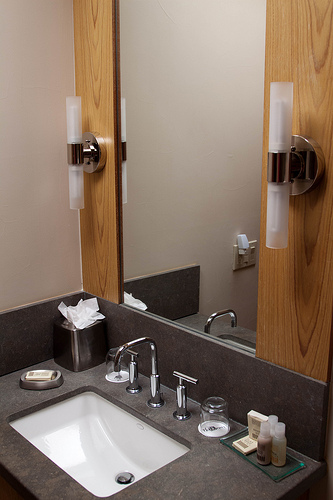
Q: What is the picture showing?
A: It is showing a bathroom.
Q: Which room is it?
A: It is a bathroom.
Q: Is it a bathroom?
A: Yes, it is a bathroom.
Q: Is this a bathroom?
A: Yes, it is a bathroom.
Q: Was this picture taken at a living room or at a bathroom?
A: It was taken at a bathroom.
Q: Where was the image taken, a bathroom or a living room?
A: It was taken at a bathroom.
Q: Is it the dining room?
A: No, it is the bathroom.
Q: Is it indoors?
A: Yes, it is indoors.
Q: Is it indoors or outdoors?
A: It is indoors.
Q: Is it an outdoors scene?
A: No, it is indoors.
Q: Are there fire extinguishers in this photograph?
A: No, there are no fire extinguishers.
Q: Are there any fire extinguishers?
A: No, there are no fire extinguishers.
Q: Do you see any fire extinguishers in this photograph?
A: No, there are no fire extinguishers.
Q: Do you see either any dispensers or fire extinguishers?
A: No, there are no fire extinguishers or dispensers.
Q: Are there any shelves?
A: No, there are no shelves.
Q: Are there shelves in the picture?
A: No, there are no shelves.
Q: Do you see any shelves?
A: No, there are no shelves.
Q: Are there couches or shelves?
A: No, there are no shelves or couches.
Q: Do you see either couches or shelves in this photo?
A: No, there are no shelves or couches.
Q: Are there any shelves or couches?
A: No, there are no shelves or couches.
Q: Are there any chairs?
A: No, there are no chairs.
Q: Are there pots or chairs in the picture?
A: No, there are no chairs or pots.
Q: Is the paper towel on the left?
A: Yes, the paper towel is on the left of the image.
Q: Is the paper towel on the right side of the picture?
A: No, the paper towel is on the left of the image.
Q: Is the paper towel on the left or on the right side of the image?
A: The paper towel is on the left of the image.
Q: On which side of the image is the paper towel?
A: The paper towel is on the left of the image.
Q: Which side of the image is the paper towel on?
A: The paper towel is on the left of the image.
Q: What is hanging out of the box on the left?
A: The paper towel is hanging out of the box.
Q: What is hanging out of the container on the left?
A: The paper towel is hanging out of the box.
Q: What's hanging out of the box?
A: The paper towel is hanging out of the box.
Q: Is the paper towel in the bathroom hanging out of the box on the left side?
A: Yes, the paper towel is hanging out of the box.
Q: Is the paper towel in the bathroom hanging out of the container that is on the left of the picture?
A: Yes, the paper towel is hanging out of the box.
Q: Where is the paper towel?
A: The paper towel is in the bathroom.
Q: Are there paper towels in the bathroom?
A: Yes, there is a paper towel in the bathroom.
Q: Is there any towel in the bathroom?
A: No, there is a paper towel in the bathroom.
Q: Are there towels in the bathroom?
A: No, there is a paper towel in the bathroom.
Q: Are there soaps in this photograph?
A: Yes, there is a soap.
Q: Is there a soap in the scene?
A: Yes, there is a soap.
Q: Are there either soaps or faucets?
A: Yes, there is a soap.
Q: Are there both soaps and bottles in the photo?
A: Yes, there are both a soap and a bottle.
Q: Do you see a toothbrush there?
A: No, there are no toothbrushes.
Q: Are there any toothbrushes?
A: No, there are no toothbrushes.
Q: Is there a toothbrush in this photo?
A: No, there are no toothbrushes.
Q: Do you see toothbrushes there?
A: No, there are no toothbrushes.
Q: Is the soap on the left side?
A: Yes, the soap is on the left of the image.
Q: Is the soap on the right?
A: No, the soap is on the left of the image.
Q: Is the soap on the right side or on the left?
A: The soap is on the left of the image.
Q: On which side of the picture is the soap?
A: The soap is on the left of the image.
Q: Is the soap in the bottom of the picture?
A: Yes, the soap is in the bottom of the image.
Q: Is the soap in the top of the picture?
A: No, the soap is in the bottom of the image.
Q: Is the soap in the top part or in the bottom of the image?
A: The soap is in the bottom of the image.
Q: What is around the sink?
A: The soap is around the sink.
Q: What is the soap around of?
A: The soap is around the sink.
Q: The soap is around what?
A: The soap is around the sink.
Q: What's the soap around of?
A: The soap is around the sink.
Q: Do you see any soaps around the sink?
A: Yes, there is a soap around the sink.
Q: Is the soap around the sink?
A: Yes, the soap is around the sink.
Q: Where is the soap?
A: The soap is in the bathroom.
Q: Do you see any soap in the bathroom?
A: Yes, there is a soap in the bathroom.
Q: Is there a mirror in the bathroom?
A: No, there is a soap in the bathroom.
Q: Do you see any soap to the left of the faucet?
A: Yes, there is a soap to the left of the faucet.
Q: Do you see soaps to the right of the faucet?
A: No, the soap is to the left of the faucet.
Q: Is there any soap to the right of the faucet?
A: No, the soap is to the left of the faucet.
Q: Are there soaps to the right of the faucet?
A: No, the soap is to the left of the faucet.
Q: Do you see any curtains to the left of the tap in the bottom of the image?
A: No, there is a soap to the left of the faucet.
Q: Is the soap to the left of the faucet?
A: Yes, the soap is to the left of the faucet.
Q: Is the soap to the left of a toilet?
A: No, the soap is to the left of the faucet.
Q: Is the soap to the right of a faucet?
A: No, the soap is to the left of a faucet.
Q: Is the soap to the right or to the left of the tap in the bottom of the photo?
A: The soap is to the left of the tap.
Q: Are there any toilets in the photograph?
A: No, there are no toilets.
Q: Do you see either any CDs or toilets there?
A: No, there are no toilets or cds.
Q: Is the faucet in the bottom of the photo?
A: Yes, the faucet is in the bottom of the image.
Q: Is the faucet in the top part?
A: No, the faucet is in the bottom of the image.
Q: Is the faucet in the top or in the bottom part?
A: The faucet is in the bottom of the image.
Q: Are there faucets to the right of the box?
A: Yes, there is a faucet to the right of the box.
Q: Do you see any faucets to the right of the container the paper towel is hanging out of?
A: Yes, there is a faucet to the right of the box.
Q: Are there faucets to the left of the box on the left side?
A: No, the faucet is to the right of the box.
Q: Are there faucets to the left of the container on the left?
A: No, the faucet is to the right of the box.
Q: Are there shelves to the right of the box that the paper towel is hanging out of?
A: No, there is a faucet to the right of the box.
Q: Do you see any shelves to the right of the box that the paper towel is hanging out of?
A: No, there is a faucet to the right of the box.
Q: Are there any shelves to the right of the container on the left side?
A: No, there is a faucet to the right of the box.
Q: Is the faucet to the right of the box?
A: Yes, the faucet is to the right of the box.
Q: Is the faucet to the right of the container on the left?
A: Yes, the faucet is to the right of the box.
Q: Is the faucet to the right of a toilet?
A: No, the faucet is to the right of the box.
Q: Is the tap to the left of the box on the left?
A: No, the tap is to the right of the box.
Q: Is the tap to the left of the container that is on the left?
A: No, the tap is to the right of the box.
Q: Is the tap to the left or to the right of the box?
A: The tap is to the right of the box.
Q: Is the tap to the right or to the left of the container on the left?
A: The tap is to the right of the box.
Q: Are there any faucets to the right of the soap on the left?
A: Yes, there is a faucet to the right of the soap.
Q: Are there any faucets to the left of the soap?
A: No, the faucet is to the right of the soap.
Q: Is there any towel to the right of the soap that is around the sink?
A: No, there is a faucet to the right of the soap.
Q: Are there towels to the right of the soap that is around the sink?
A: No, there is a faucet to the right of the soap.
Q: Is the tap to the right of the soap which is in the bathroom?
A: Yes, the tap is to the right of the soap.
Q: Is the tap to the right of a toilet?
A: No, the tap is to the right of the soap.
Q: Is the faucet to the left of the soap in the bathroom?
A: No, the faucet is to the right of the soap.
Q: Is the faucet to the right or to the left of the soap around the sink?
A: The faucet is to the right of the soap.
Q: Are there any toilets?
A: No, there are no toilets.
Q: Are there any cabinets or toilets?
A: No, there are no toilets or cabinets.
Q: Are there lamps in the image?
A: Yes, there is a lamp.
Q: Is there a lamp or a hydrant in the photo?
A: Yes, there is a lamp.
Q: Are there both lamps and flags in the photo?
A: No, there is a lamp but no flags.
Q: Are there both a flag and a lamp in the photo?
A: No, there is a lamp but no flags.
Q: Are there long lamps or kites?
A: Yes, there is a long lamp.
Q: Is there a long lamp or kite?
A: Yes, there is a long lamp.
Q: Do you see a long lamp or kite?
A: Yes, there is a long lamp.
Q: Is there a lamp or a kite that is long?
A: Yes, the lamp is long.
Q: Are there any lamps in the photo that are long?
A: Yes, there is a long lamp.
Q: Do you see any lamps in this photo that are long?
A: Yes, there is a lamp that is long.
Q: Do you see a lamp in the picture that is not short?
A: Yes, there is a long lamp.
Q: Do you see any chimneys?
A: No, there are no chimneys.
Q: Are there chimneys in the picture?
A: No, there are no chimneys.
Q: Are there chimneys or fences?
A: No, there are no chimneys or fences.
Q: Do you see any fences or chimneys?
A: No, there are no chimneys or fences.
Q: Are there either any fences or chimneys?
A: No, there are no chimneys or fences.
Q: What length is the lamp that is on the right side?
A: The lamp is long.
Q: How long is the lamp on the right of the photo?
A: The lamp is long.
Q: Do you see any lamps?
A: Yes, there is a lamp.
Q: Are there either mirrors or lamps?
A: Yes, there is a lamp.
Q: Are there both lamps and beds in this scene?
A: No, there is a lamp but no beds.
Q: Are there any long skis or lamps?
A: Yes, there is a long lamp.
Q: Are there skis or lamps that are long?
A: Yes, the lamp is long.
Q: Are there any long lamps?
A: Yes, there is a long lamp.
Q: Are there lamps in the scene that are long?
A: Yes, there is a lamp that is long.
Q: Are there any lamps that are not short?
A: Yes, there is a long lamp.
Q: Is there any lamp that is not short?
A: Yes, there is a long lamp.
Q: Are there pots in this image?
A: No, there are no pots.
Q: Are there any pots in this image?
A: No, there are no pots.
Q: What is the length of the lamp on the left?
A: The lamp is long.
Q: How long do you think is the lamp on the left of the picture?
A: The lamp is long.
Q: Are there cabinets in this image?
A: No, there are no cabinets.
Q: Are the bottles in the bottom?
A: Yes, the bottles are in the bottom of the image.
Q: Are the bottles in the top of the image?
A: No, the bottles are in the bottom of the image.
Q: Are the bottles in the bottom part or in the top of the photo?
A: The bottles are in the bottom of the image.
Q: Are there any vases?
A: No, there are no vases.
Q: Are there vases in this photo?
A: No, there are no vases.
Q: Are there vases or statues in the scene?
A: No, there are no vases or statues.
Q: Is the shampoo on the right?
A: Yes, the shampoo is on the right of the image.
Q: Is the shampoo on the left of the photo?
A: No, the shampoo is on the right of the image.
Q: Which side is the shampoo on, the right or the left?
A: The shampoo is on the right of the image.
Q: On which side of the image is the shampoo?
A: The shampoo is on the right of the image.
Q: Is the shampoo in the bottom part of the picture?
A: Yes, the shampoo is in the bottom of the image.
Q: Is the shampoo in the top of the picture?
A: No, the shampoo is in the bottom of the image.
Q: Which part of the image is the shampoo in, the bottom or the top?
A: The shampoo is in the bottom of the image.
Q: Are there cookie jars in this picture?
A: No, there are no cookie jars.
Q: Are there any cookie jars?
A: No, there are no cookie jars.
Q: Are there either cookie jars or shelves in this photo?
A: No, there are no cookie jars or shelves.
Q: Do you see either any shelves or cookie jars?
A: No, there are no cookie jars or shelves.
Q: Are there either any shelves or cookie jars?
A: No, there are no cookie jars or shelves.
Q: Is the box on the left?
A: Yes, the box is on the left of the image.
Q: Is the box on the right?
A: No, the box is on the left of the image.